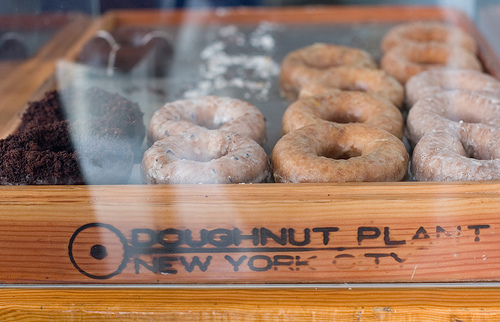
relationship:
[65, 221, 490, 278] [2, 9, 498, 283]
logo on tray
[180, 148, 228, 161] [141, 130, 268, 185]
hole in donut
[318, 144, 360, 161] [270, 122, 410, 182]
hole in donut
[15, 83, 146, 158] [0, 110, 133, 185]
donut next to donut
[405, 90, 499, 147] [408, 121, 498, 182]
donut next to donut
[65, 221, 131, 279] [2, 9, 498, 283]
donut on tray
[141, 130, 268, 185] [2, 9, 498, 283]
donut in tray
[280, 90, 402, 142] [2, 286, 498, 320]
donut on counter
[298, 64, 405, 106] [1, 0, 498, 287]
donut behind glass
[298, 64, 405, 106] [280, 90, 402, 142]
donut next to donut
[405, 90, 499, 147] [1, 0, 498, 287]
donut behind glass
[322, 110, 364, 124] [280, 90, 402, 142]
hole in donut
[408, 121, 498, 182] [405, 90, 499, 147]
donut next to donut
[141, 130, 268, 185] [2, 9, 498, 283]
donut on tray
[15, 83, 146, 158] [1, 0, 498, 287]
donut behind glass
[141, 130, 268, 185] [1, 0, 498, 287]
donut behind glass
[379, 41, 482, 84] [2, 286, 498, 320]
donut behind counter